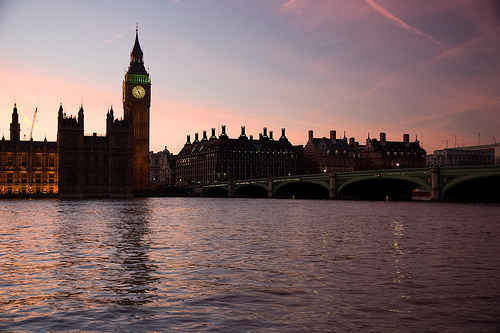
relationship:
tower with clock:
[125, 25, 157, 190] [128, 82, 147, 102]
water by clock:
[5, 199, 500, 331] [128, 82, 147, 102]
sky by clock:
[152, 9, 499, 96] [128, 82, 147, 102]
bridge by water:
[183, 165, 495, 204] [5, 199, 500, 331]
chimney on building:
[184, 127, 194, 146] [172, 145, 293, 180]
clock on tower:
[128, 82, 147, 102] [125, 25, 157, 190]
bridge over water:
[183, 165, 495, 204] [5, 199, 500, 331]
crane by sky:
[25, 102, 44, 141] [152, 9, 499, 96]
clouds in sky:
[305, 4, 491, 119] [152, 9, 499, 96]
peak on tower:
[133, 24, 141, 43] [125, 25, 157, 190]